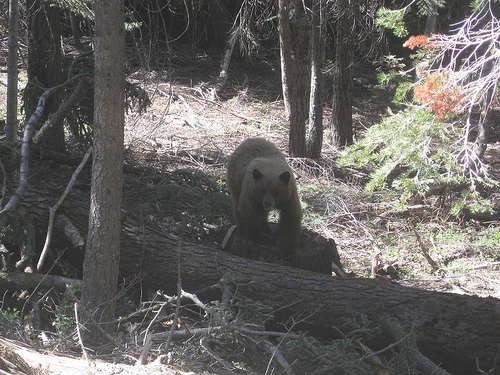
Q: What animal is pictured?
A: Bear.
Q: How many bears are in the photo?
A: One.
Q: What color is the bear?
A: Brown.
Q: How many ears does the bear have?
A: Two.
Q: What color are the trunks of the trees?
A: Brown.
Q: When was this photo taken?
A: Day time.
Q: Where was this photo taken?
A: The woods.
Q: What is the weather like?
A: Sunny.